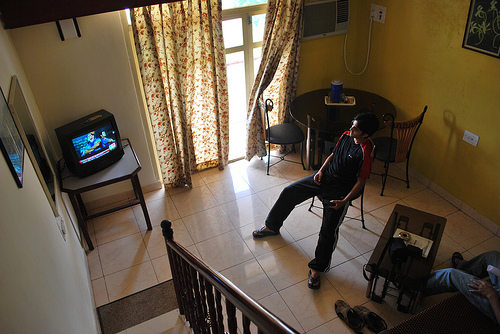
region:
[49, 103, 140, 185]
television is on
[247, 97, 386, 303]
man sitting in chair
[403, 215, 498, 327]
man sitting on couch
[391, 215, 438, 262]
magazine on coffee table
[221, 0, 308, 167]
curtain is open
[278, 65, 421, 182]
table is in the corner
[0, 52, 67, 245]
two pictures on left wall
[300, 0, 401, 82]
air conditioner next to curtain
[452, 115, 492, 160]
power outlet on right wall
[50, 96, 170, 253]
television sitting on table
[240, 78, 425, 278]
a person sitting in a chair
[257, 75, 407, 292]
a man sitting in a chair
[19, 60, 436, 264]
a man watching television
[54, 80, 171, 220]
a television turned on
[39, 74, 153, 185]
a television that is small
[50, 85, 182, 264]
a television sitting on a small table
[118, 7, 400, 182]
window with curtains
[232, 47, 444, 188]
a small circle table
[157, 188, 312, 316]
floor that is tile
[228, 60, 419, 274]
a man wearing flipflops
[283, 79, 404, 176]
round table in the corner of the room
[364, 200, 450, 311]
black glass coffee table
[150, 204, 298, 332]
wood banaster going upstairs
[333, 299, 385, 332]
pair of slip on shoes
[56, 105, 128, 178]
small black box tv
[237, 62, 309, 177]
chair holding the curtain shut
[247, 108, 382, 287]
person sitting in chair holding a remote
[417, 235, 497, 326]
person sitting on the couch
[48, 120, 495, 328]
square tiles make up the floor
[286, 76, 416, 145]
black glass round table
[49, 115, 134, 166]
small tv on table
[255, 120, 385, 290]
person sitting in chair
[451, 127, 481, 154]
white outlet on wall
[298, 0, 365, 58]
air conditioner in wall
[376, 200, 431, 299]
coffee table in room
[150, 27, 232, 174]
floral curtain panel on window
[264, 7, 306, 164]
floral curtain panel on window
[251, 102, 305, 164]
black metal chair at table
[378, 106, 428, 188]
black metal chair at table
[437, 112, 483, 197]
shadow on yellow wall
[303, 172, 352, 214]
Remote in his left hand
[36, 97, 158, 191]
Old style tv on the table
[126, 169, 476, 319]
Tiles on the floor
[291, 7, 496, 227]
Walls painted mustard yellow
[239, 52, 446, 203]
Round table and two chairs in the corner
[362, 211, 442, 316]
Bunch of stuff on coffee table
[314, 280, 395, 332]
Sneakers sitting on the floor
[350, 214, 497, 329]
Friend on couch with controller in hand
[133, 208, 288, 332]
Wooden rail going up the staircase